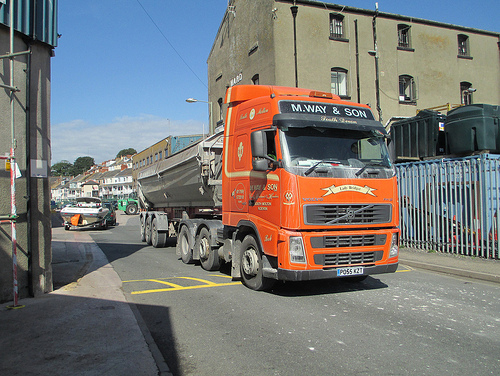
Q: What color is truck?
A: Orange.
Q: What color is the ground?
A: Grey.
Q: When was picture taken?
A: Daytime.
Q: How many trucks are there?
A: One.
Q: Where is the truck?
A: Street.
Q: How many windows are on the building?
A: Eight.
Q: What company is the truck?
A: M. Way and son.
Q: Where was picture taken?
A: At the intersection.